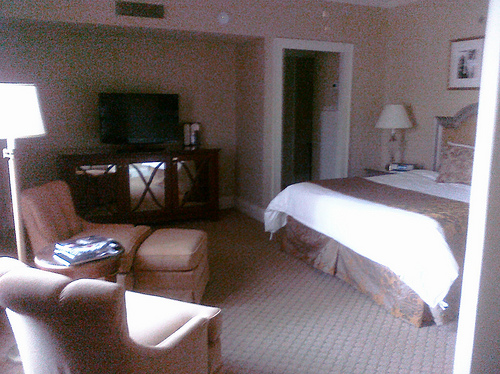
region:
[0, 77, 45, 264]
a floor lamp is lit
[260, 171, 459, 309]
an extra blanket is folded at the foot of the bed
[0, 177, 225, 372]
two champaigne colored chairs with matching ottoman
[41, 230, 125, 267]
sack of magazines on end table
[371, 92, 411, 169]
a glass table top lamy with white shade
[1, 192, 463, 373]
the room has wall to wall carpeting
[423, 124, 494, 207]
an accent pillow that matches the bedspread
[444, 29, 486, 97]
a white matted picture in a wood frame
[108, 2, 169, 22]
a vent near the ceiling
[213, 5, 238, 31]
a white fire alarm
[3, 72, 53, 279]
lamp between two chairs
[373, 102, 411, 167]
lamp on bedside table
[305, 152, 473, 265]
brown blanket draped over the bed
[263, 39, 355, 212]
white frame of doorway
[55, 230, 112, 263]
stack of magazines on round table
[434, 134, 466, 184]
pillows propped on the bed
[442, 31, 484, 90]
picture hung above bed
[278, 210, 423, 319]
bed skirt on the bed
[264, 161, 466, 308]
white comforter on the bed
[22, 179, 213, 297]
chair and ottoman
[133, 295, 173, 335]
Light shining from the window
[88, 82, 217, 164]
Flat screen tv on stand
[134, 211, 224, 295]
Foot stool in front of chair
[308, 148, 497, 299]
The bed is made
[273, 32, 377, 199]
Doorway going in to bathroom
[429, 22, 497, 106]
Picture on the wall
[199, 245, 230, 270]
Shadow on the ground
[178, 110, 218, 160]
Books sitting on the stand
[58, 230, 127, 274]
Magazines on the table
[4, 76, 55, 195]
Lamp standing on the floor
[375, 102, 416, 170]
table lamp to the left of a bed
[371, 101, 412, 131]
white lampshade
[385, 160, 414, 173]
nook beside table lamp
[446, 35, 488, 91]
picture hanging above bed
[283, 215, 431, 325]
brown bedskirt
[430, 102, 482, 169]
brown headboard touching the wall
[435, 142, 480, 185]
brown pillow leaning against headboard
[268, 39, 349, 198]
doorway to the left of the bed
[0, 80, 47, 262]
floor lamp is on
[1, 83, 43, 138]
white lamp shade on top of floor lamp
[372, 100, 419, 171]
a tall table lamp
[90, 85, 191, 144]
a large black t.v.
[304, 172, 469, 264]
a long brown blanket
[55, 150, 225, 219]
a brown t.v. cabinet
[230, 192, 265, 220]
white floor trim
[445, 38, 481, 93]
part of picture frame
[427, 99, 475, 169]
part of a headboard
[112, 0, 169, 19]
a long ac vent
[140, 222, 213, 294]
a chair ottoman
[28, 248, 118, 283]
part of a small brown table